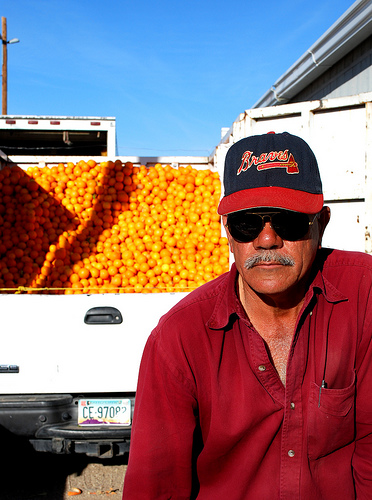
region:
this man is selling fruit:
[6, 24, 338, 318]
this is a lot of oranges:
[16, 165, 228, 351]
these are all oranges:
[33, 180, 183, 308]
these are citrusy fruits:
[9, 170, 210, 310]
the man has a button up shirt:
[154, 278, 357, 496]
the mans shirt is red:
[145, 294, 370, 463]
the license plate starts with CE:
[65, 391, 99, 425]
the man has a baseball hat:
[238, 144, 357, 269]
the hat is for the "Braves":
[216, 128, 334, 208]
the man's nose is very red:
[204, 211, 319, 250]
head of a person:
[202, 130, 335, 302]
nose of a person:
[252, 228, 284, 252]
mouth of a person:
[250, 255, 294, 276]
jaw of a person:
[249, 274, 293, 294]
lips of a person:
[250, 253, 286, 269]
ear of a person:
[316, 204, 337, 251]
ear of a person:
[214, 214, 231, 248]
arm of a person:
[121, 363, 204, 496]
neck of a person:
[233, 282, 297, 340]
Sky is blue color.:
[29, 11, 256, 85]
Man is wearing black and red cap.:
[222, 135, 323, 231]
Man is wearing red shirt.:
[128, 182, 367, 474]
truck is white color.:
[8, 110, 223, 353]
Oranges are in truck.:
[12, 154, 204, 293]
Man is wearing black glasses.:
[196, 130, 337, 293]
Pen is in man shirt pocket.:
[307, 370, 332, 412]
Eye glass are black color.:
[207, 196, 312, 247]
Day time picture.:
[11, 15, 342, 496]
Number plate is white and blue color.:
[75, 396, 133, 439]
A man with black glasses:
[211, 148, 333, 496]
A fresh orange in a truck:
[178, 258, 202, 272]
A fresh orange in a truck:
[98, 257, 107, 275]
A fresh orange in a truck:
[137, 259, 154, 271]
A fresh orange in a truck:
[77, 258, 92, 281]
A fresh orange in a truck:
[170, 172, 191, 184]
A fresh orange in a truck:
[54, 171, 69, 182]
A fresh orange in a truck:
[199, 174, 204, 184]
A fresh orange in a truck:
[19, 265, 36, 272]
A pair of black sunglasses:
[213, 201, 322, 244]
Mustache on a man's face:
[234, 241, 297, 277]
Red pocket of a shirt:
[297, 359, 359, 464]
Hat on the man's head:
[208, 120, 338, 297]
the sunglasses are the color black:
[227, 211, 312, 243]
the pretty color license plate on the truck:
[76, 395, 132, 427]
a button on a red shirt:
[254, 358, 266, 375]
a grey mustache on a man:
[241, 250, 292, 267]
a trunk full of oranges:
[1, 159, 226, 288]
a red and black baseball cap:
[218, 130, 324, 219]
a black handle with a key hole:
[81, 305, 122, 324]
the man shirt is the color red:
[123, 248, 369, 498]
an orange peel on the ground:
[66, 484, 117, 497]